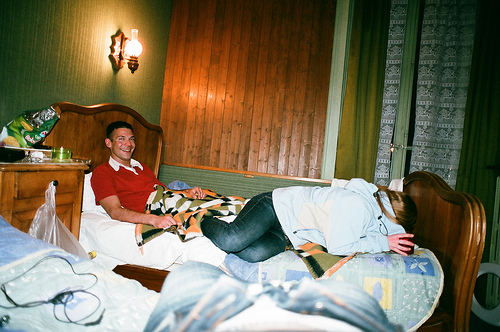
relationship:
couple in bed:
[96, 129, 416, 256] [45, 100, 477, 326]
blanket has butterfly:
[228, 246, 443, 324] [407, 258, 426, 273]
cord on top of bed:
[7, 257, 109, 324] [4, 227, 281, 331]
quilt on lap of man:
[146, 188, 242, 246] [93, 125, 205, 231]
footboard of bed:
[410, 173, 485, 332] [45, 100, 477, 326]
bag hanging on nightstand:
[36, 184, 82, 259] [6, 159, 88, 253]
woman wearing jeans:
[206, 183, 415, 259] [196, 193, 289, 263]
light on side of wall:
[113, 27, 142, 73] [3, 3, 175, 113]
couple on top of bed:
[96, 129, 416, 256] [45, 100, 477, 326]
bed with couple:
[45, 100, 477, 326] [96, 129, 416, 256]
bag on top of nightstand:
[4, 108, 56, 146] [6, 159, 88, 253]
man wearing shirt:
[93, 125, 205, 231] [91, 165, 170, 210]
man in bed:
[93, 125, 205, 231] [45, 100, 477, 326]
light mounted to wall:
[113, 27, 142, 73] [3, 3, 175, 113]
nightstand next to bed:
[6, 159, 88, 253] [45, 100, 477, 326]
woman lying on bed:
[206, 183, 415, 259] [45, 100, 477, 326]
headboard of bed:
[51, 103, 162, 172] [45, 100, 477, 326]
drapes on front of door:
[373, 3, 470, 193] [406, 9, 484, 208]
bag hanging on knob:
[36, 184, 82, 259] [50, 180, 61, 186]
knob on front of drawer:
[50, 180, 61, 186] [13, 172, 78, 194]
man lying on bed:
[93, 125, 205, 231] [45, 100, 477, 326]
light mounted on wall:
[113, 27, 142, 73] [3, 3, 175, 113]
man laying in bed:
[93, 125, 205, 231] [45, 100, 477, 326]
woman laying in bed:
[206, 183, 415, 259] [45, 100, 477, 326]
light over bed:
[113, 27, 142, 73] [45, 100, 477, 326]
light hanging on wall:
[113, 27, 142, 73] [3, 3, 175, 113]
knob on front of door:
[387, 140, 416, 154] [406, 9, 484, 208]